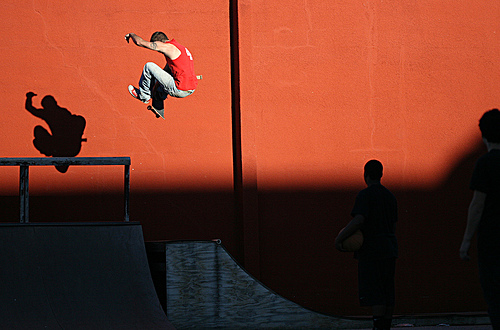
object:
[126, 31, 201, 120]
skateboarder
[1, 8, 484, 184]
wall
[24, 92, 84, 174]
shadow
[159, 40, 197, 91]
shirt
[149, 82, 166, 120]
skateboard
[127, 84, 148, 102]
sneaker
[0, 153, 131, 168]
bars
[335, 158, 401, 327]
spectator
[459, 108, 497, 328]
man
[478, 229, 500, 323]
jeans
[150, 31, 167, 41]
hair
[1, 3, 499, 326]
skatepark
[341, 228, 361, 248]
ball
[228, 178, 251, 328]
half pipe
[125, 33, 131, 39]
watch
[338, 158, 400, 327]
2 people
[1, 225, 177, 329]
ramp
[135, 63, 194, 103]
jeans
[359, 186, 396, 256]
t-shirt